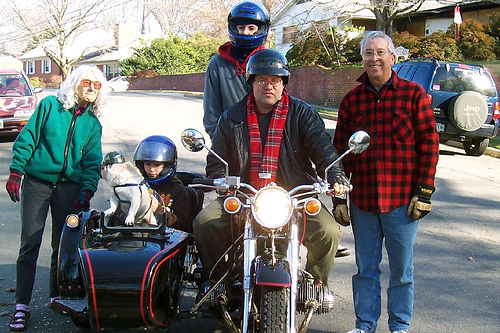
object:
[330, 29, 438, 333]
man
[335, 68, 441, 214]
shirt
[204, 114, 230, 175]
arm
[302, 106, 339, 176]
arm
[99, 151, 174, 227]
dog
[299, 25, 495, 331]
person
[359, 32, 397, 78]
head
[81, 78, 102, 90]
sunglasses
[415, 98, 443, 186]
arm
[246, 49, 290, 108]
head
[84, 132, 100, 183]
arm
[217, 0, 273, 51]
helmet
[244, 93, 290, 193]
redscarf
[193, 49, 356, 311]
man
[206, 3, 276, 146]
person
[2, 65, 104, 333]
person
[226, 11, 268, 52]
head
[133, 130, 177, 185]
head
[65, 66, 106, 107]
head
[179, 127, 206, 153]
mirror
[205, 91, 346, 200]
jacket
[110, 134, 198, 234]
person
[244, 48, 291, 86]
helmet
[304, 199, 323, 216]
light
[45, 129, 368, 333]
cycle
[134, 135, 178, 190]
helmet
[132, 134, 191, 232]
boy